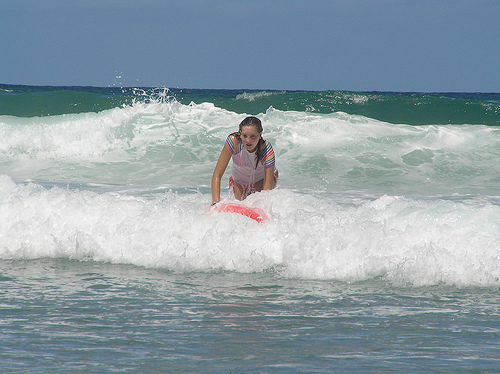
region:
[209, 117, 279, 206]
A girl with brown hair on a surfboard.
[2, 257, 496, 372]
Calmer rippled water in front of the waves.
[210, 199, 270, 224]
Orange surfboard a girl is on.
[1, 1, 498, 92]
A dark blue sky.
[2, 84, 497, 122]
Greenest section of water.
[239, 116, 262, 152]
Head of a girl on a surfboard.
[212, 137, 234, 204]
Right arm of a girl surfer.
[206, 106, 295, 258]
Woman in the water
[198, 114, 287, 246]
Woman on a surfboard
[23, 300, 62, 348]
Small ripples in the water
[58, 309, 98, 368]
Small ripples in the water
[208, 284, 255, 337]
Small ripples in the water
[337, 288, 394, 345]
Small ripples in the water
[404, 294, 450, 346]
Small ripples in the water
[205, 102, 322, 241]
Girl in the water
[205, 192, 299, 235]
Red surfboard in the water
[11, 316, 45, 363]
Small ripples in the water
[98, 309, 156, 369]
Small ripples in the water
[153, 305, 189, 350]
Small ripples in the water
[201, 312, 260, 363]
Small ripples in the water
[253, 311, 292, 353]
Small ripples in the water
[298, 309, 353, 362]
Small ripples in the water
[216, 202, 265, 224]
The red surfboard the girl is using.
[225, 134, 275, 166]
The stripes of the girl's shirt.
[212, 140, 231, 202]
The left arm of the girl.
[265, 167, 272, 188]
The right arm of the girl.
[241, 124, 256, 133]
The forehead of the girl.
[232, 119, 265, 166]
The hair of the girl.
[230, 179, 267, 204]
The thighs of the girl's legs.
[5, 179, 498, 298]
The wave in front of the girl.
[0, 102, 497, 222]
The wave behind the girl.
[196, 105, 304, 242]
girl on surf board in wave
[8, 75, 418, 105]
dark blue water on horizon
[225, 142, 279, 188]
white and striped suit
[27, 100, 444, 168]
rolling wave behind surfer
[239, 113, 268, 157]
girl with brunette hair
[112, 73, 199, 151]
spray from wave behind surfer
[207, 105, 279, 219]
girl with long hair on board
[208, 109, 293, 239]
a female on a surf board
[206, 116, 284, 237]
a female wearing pink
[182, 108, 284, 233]
a female surfing in the ocean